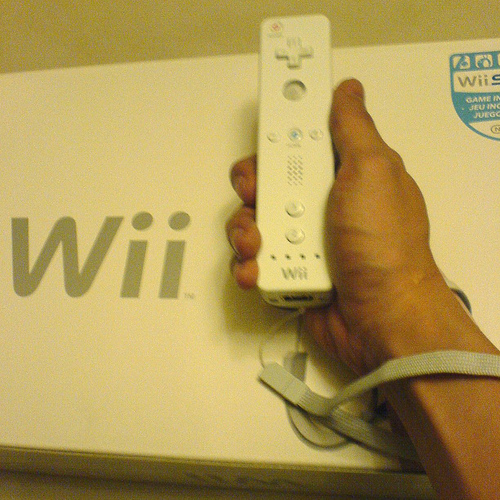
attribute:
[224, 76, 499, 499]
hand — existing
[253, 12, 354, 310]
remote control — white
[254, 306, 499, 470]
strap — gray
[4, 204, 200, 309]
word — gray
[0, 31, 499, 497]
wii — white, cardboard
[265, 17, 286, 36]
power button — red, blue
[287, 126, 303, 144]
home button — blue